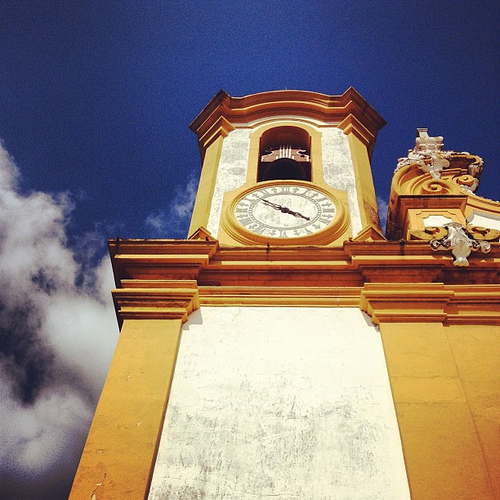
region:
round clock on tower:
[232, 178, 347, 247]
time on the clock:
[238, 180, 337, 237]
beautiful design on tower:
[393, 123, 495, 268]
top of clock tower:
[190, 77, 391, 156]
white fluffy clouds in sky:
[14, 148, 87, 365]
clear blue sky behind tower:
[66, 88, 151, 175]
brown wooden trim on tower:
[100, 226, 496, 326]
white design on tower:
[431, 223, 486, 272]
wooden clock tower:
[114, 80, 412, 499]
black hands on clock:
[252, 198, 313, 226]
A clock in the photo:
[232, 165, 337, 236]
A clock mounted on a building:
[216, 189, 348, 237]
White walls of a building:
[183, 333, 337, 470]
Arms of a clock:
[253, 192, 323, 222]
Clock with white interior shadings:
[230, 182, 341, 236]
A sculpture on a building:
[394, 121, 498, 256]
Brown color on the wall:
[416, 355, 497, 480]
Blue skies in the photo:
[53, 138, 164, 203]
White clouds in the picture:
[1, 219, 86, 372]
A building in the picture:
[176, 294, 483, 467]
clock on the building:
[203, 160, 348, 273]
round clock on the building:
[217, 157, 360, 253]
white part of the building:
[205, 350, 337, 429]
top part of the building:
[184, 58, 386, 145]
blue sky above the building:
[58, 38, 146, 118]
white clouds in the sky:
[7, 158, 82, 278]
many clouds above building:
[0, 195, 107, 384]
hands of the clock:
[258, 185, 318, 231]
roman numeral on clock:
[268, 178, 300, 198]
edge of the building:
[91, 220, 156, 271]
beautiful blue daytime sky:
[148, 103, 193, 173]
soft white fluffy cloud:
[47, 325, 99, 400]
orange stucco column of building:
[127, 383, 144, 418]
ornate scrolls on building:
[433, 216, 487, 291]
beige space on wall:
[220, 376, 293, 447]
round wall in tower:
[241, 192, 346, 267]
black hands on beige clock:
[253, 199, 336, 261]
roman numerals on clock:
[248, 211, 268, 242]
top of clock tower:
[213, 104, 357, 151]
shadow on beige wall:
[183, 305, 228, 340]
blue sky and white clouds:
[8, 143, 95, 258]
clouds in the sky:
[8, 140, 96, 259]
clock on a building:
[224, 173, 355, 245]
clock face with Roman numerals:
[226, 178, 346, 246]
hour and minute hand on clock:
[221, 178, 351, 245]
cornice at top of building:
[99, 234, 446, 320]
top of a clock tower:
[181, 70, 389, 248]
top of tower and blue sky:
[180, 28, 400, 149]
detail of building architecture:
[391, 121, 498, 266]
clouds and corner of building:
[34, 214, 185, 328]